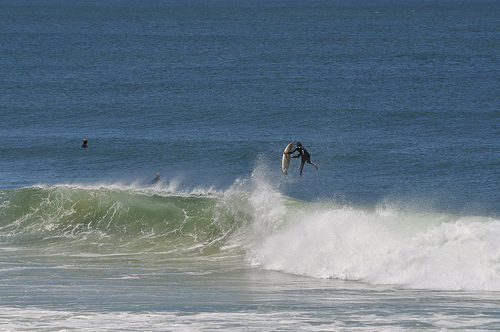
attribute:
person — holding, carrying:
[288, 127, 314, 172]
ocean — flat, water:
[131, 17, 256, 103]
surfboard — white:
[276, 129, 296, 171]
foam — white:
[156, 202, 213, 253]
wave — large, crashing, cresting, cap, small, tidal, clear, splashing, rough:
[378, 203, 469, 272]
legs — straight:
[297, 161, 321, 171]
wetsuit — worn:
[281, 139, 319, 159]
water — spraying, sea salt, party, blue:
[182, 0, 200, 9]